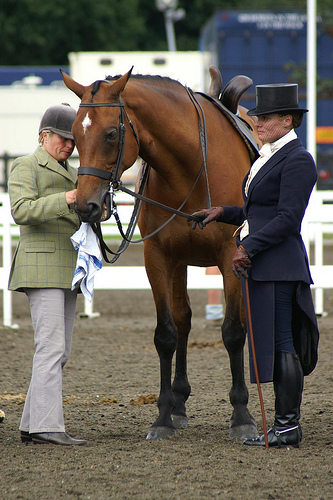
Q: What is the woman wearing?
A: A suit.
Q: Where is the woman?
A: On the field.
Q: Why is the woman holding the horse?
A: Preparing the horse.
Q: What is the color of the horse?
A: Brown.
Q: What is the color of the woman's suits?
A: Blue and white.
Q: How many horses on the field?
A: One.